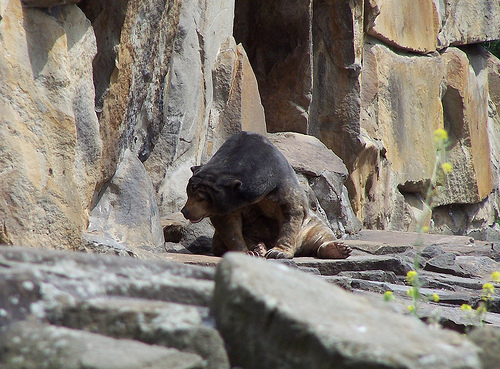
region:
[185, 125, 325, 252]
a bear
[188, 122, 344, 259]
a bear sitting down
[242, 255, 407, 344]
a rock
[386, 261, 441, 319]
flowers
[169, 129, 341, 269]
bear is brown and black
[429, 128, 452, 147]
yellow flower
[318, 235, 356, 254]
bears foot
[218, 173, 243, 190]
bears ear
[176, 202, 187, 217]
the bears nose is black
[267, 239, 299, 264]
the bears hand on the ground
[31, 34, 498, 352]
This is taken outside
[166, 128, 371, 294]
this is a bear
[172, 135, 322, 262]
this bear is brown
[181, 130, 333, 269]
the bear has short hair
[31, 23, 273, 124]
the wall is made of stone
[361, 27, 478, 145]
the wall is red, gray, and black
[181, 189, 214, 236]
the bear's mouth is open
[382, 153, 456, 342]
these are wildflowers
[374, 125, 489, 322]
the flowers are yellow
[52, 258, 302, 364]
there are flat rocks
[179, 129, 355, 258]
a bear on a rock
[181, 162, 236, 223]
the head of a bear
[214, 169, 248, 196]
the ear of a bear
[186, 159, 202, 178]
the ear of a bear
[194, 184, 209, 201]
an eye of a bear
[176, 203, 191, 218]
the nose of a bear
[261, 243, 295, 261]
a paw of a bear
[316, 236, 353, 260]
the bottom of the hind paw of a bear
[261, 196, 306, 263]
the front leg of a bear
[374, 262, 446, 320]
yellow flowers growing out ot the rocks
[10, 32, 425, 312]
this could be at a zoo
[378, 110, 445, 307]
the flower is yellow and green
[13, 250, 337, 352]
the rocks are out of focus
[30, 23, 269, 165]
the rocks here are red and gray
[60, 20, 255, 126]
these rocks have cracks in them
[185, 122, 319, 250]
this bear is black and brown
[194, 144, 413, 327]
the bear is sitting down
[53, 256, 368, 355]
these rocks are light gray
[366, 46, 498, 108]
these rocks are huge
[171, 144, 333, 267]
the bear is panting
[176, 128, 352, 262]
bear sitting on rocks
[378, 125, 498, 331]
closeup of yellow and green weed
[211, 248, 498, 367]
large boulder in foreground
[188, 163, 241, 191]
ears of bear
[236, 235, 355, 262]
paws of the brown bear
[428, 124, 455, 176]
two yellow flowers of weed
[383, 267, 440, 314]
yellow flowers of weed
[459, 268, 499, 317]
yellow flowers of weed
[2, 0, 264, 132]
rocks in the background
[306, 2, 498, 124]
rocks in the background